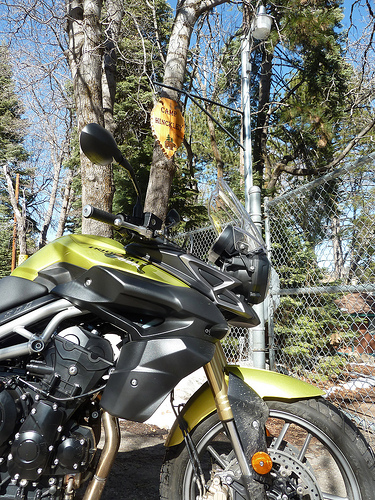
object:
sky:
[0, 1, 375, 247]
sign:
[150, 96, 185, 159]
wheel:
[159, 394, 373, 498]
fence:
[167, 154, 375, 441]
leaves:
[268, 0, 366, 162]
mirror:
[80, 124, 119, 166]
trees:
[0, 0, 375, 242]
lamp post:
[241, 5, 265, 371]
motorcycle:
[0, 122, 375, 500]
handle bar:
[83, 204, 138, 239]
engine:
[0, 328, 106, 497]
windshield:
[208, 177, 265, 252]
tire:
[160, 381, 374, 499]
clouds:
[0, 1, 375, 112]